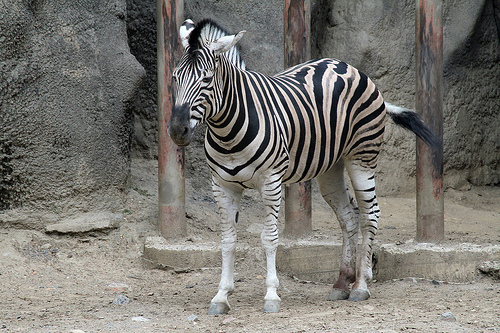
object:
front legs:
[210, 174, 284, 289]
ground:
[1, 178, 500, 332]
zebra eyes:
[171, 75, 210, 84]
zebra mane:
[186, 17, 248, 73]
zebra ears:
[178, 18, 248, 54]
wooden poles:
[154, 0, 449, 246]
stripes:
[260, 58, 388, 163]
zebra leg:
[345, 160, 381, 281]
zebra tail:
[385, 103, 444, 152]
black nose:
[169, 104, 191, 145]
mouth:
[173, 134, 194, 147]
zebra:
[170, 13, 447, 315]